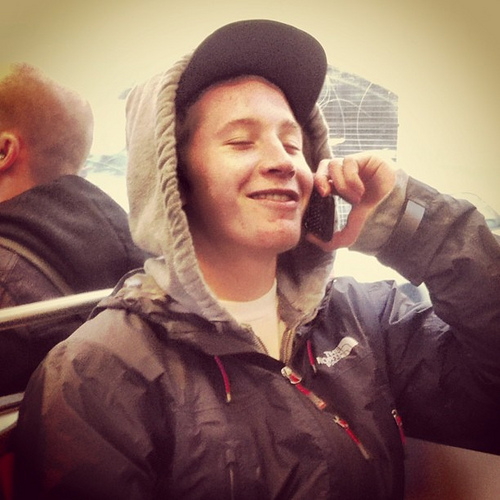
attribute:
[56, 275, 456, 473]
jacket — hooded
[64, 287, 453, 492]
jacket — numerous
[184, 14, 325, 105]
cap — baseball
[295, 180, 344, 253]
phone — cell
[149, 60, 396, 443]
character — main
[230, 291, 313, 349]
shirt — white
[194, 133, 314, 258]
guy — smiling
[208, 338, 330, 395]
ties — hood, red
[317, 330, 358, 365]
logo — manufactures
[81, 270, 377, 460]
jacket — Northface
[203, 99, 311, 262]
face — smiling, man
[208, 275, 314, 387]
shirt — white, t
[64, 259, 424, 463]
breaker — black, wind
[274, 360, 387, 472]
zipper — red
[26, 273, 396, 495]
breaker — wind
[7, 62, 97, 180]
head — back, person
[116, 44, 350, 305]
hoodie — grey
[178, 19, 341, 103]
cap — black, baseball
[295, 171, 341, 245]
phone — cell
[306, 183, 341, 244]
phone — black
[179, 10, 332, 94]
cap — black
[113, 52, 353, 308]
hood — gray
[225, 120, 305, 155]
eyes — man's, closed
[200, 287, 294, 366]
shirt — white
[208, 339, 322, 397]
strings — red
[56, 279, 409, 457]
jacket — black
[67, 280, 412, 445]
jacket — northface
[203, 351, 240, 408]
string — red, pull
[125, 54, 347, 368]
boy — young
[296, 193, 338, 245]
phone — his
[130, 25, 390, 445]
man — young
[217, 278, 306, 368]
shirt — white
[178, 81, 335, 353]
boy — young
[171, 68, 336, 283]
guy — young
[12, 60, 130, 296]
guy — back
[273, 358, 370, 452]
zipper — red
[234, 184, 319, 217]
grin — goofy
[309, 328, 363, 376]
logo — brand name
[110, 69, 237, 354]
hoodie — grey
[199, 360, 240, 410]
tie pull — red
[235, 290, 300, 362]
t-shirt — white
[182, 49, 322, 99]
hat — blue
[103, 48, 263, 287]
hoodie — grey